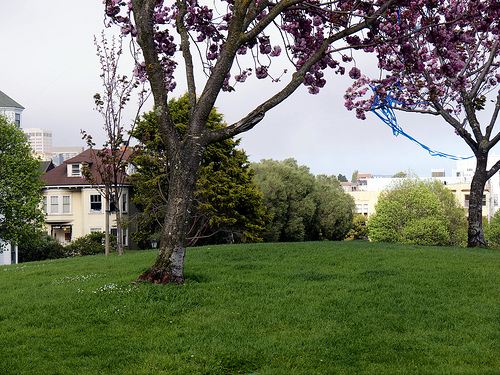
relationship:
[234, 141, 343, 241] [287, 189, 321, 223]
trees are green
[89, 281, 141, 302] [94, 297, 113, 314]
white flowers in grass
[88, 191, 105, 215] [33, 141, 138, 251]
window on building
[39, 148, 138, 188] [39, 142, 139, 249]
roof on house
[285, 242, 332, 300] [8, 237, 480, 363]
part of a ground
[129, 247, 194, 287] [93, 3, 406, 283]
base of a tree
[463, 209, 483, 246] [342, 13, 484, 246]
part of a tree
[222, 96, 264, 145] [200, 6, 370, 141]
part of a branch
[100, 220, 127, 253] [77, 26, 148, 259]
part of a post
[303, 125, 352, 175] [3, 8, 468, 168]
part of sky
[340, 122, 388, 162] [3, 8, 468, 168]
part of sky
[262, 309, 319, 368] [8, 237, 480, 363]
part of a ground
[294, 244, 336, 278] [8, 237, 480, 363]
part of a ground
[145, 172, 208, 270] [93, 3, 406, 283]
stem of a tree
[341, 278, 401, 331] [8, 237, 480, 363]
part of a ground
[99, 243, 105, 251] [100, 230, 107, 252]
part of a post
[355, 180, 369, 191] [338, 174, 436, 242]
part of a building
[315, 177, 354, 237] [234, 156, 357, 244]
edge of a trees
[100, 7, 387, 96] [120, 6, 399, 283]
blossoms on tree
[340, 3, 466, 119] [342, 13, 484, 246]
blossoms on tree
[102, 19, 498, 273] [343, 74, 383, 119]
two trees with purple flowers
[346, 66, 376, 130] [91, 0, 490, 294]
purple flowers on two trees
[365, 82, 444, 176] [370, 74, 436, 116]
blue kite twine in tree limbs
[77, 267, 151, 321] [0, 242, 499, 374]
white flowers in green lawn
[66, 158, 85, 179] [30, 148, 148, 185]
window on roof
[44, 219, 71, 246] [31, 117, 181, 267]
back porch to house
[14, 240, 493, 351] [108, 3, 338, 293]
green lawn containing trees